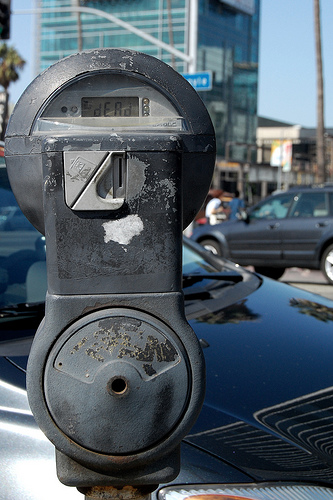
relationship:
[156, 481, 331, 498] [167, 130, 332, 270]
headlight of car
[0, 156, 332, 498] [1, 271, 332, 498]
car has hood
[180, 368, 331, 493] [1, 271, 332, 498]
reflection on hood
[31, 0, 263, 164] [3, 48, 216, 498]
building with meter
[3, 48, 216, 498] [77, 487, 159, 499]
meter on post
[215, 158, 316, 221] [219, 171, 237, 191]
building has window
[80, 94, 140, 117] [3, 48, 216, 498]
screen on meter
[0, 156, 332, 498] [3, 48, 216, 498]
car behind meter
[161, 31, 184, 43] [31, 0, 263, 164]
window on building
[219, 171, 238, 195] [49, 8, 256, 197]
window on a building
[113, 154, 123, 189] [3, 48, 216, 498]
coin slot on meter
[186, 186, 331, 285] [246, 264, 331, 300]
car on street